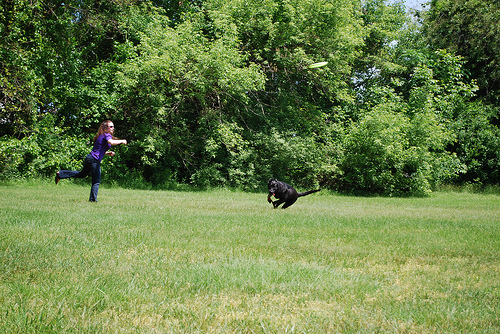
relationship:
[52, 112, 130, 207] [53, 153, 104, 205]
girl wearing jeans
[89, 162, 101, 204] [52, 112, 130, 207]
leg on woman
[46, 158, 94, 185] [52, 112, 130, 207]
leg on woman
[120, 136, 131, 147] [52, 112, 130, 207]
hand of woman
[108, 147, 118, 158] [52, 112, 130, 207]
hand on woman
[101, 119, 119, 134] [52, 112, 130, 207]
head on woman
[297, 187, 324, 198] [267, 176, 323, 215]
tail on dog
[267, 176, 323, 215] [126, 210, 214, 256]
dog on grass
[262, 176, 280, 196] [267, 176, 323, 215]
head on dog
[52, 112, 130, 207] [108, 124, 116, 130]
woman wearing sunglasses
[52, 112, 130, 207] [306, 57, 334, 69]
girl throwing frisbee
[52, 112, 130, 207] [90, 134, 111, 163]
girl wearing shirt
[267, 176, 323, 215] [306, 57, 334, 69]
dog chasing frisbee